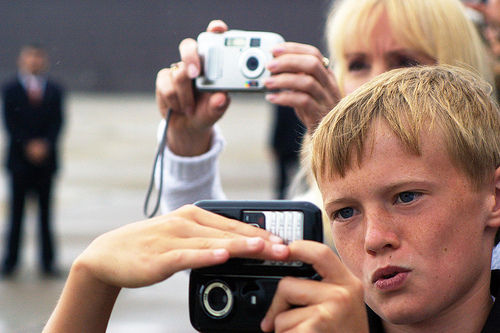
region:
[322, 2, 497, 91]
Woman has light hair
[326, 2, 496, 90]
Woman has blond hair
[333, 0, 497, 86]
Woman's hair is straight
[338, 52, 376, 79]
Woman has dark eye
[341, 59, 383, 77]
Woman's eye is brown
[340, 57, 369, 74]
Woman's eye is open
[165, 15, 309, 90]
Woman holding silver camera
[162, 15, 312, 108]
Woman preparing to take picture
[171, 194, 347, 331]
Boy holding cell phone.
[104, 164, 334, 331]
Boy taking picture using cell phone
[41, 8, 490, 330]
Two people are trying to take a picture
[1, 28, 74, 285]
This scene have a blurry man standing in the background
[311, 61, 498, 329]
Young boy have blue eyes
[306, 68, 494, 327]
Young boy have blonde hair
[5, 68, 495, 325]
Young boy holding a black camera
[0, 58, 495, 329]
Young boy aiming focus on a scene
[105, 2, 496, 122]
Woman holding a camera behind young boy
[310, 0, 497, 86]
Woman that have blonde hair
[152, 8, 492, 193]
Woman holding silver camera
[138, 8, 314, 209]
Silver camera has a black strap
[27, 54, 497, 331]
young boy holding a cellphone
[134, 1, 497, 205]
older woman holding a camera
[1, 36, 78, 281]
man wearing a black suit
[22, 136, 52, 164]
hands clasped together in front of the body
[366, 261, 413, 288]
mouth slightly open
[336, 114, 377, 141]
tuft of blond hair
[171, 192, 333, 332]
silver cellphone in a black case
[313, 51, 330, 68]
large gold ring on the pointer finger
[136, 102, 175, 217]
long thin strap of the camera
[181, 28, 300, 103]
silver camera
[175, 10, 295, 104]
She has a silver camera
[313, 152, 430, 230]
His eyes are blue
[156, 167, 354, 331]
His phone doubles as a camera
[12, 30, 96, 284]
There is a man in the background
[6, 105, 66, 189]
The man has his hands together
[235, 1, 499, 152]
The woman is blonde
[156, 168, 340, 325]
This phone is black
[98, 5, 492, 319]
Both people are Caucasian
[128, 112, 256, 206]
Her shirt is white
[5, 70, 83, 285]
This man's suit is black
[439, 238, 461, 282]
BOY HAS BLACK MOLE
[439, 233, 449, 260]
BOY HAS BLACK MOLE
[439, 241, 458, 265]
BOY HAS BLACK MOLE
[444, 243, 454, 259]
BOY HAS BLACK MOLE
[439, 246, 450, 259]
BOY HAS BLACK MOLE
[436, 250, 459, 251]
BOY HAS BLACK MOLE